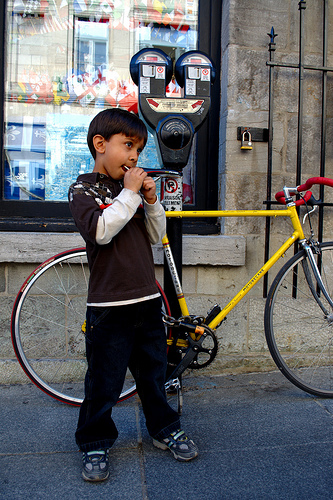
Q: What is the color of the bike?
A: Yellow.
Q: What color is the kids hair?
A: Black.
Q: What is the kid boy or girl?
A: Boy.